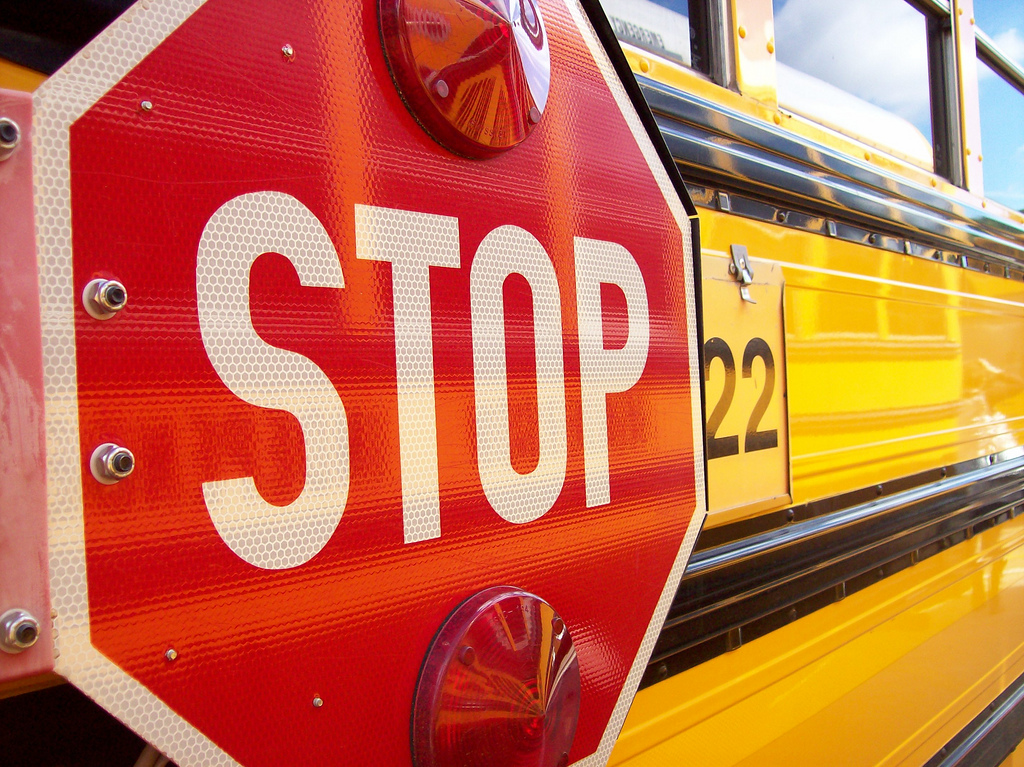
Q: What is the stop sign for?
A: To stop traffic.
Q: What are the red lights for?
A: To make the drivers see the sign.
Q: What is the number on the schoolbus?
A: 22.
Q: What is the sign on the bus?
A: Stop sign.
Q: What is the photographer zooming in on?
A: The stop sign.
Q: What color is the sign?
A: Red and white.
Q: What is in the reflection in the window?
A: Another bus.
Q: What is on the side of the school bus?
A: Stop sign.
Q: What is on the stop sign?
A: A red reflector.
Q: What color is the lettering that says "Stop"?
A: White.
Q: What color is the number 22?
A: Black.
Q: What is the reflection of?
A: A school bus.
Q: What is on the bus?
A: Windows.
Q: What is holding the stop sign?
A: Fasteners.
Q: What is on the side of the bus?
A: Black stripes.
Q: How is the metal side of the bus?
A: It is ridged.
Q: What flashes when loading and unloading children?
A: A red light.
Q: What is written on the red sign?
A: The word stop.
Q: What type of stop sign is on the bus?
A: An octagonal red and white sign.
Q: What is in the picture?
A: The side of a yellow school bus.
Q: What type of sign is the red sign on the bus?
A: A stop sign.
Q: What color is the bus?
A: Yellow.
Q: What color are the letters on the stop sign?
A: White.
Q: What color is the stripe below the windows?
A: Black.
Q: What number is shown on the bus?
A: 22.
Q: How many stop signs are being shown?
A: One.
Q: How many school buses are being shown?
A: One.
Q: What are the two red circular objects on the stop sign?
A: Lights.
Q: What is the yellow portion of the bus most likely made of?
A: Metal.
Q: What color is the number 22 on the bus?
A: Black.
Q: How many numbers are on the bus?
A: 2.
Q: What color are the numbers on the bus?
A: Black.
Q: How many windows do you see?
A: 3.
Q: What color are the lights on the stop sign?
A: Red.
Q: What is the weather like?
A: Sunny.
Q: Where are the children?
A: On the bus.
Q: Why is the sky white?
A: There are clouds out.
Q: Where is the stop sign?
A: On the school bus.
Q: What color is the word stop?
A: White.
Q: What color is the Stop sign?
A: Red.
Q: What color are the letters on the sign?
A: White.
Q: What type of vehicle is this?
A: Bus.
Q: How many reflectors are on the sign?
A: Two.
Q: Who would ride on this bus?
A: Children.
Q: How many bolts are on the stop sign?
A: Two.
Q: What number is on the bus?
A: 22.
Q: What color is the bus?
A: Yellow and black.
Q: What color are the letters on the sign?
A: White.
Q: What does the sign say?
A: Stop.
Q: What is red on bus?
A: Stop sign.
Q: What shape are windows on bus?
A: Rectangle.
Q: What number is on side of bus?
A: 22.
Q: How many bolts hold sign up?
A: 2.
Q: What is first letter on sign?
A: S.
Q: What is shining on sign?
A: Reflection.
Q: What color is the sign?
A: Red and white.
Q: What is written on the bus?
A: 22.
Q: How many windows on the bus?
A: 3.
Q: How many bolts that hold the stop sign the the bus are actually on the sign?
A: 2.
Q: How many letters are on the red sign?
A: 4.